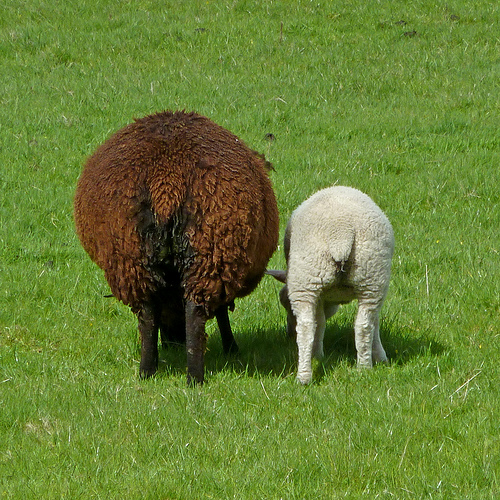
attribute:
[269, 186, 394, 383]
sheep — in the field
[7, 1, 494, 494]
grass — in field, green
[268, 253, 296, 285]
ear — white, pointy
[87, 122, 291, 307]
wool — on sheep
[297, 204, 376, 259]
wool — on sheep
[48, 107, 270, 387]
sheep — brown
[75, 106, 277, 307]
butt — sheep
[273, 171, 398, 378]
sheep — one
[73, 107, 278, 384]
animal — in field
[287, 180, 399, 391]
sheep — in field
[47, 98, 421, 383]
sheep — in field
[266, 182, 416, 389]
animal — in field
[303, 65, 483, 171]
grass — in field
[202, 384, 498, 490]
grass — green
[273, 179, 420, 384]
sheep — white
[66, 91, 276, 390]
big sheep — one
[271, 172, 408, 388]
little sheep — one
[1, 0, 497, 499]
field — grass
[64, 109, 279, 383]
sheep — one, brown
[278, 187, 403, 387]
sheep — one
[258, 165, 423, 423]
sheep — white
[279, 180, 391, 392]
plate — small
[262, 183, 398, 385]
sheep — one, white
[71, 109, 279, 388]
large sheep — brown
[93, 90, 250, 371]
sheep — big, brown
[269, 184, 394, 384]
white sheep — little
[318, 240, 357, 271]
tail — little, white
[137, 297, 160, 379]
leg — in field